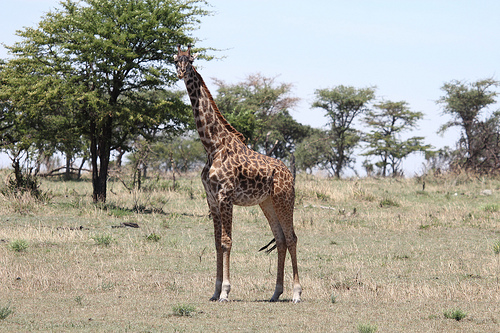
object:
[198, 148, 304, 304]
body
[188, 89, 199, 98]
spot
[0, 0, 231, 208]
trees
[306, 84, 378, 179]
trees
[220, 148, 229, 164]
spot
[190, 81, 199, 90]
spot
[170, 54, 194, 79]
face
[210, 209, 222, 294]
legs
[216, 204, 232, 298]
legs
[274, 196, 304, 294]
back legs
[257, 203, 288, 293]
back legs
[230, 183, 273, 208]
belly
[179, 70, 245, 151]
long neck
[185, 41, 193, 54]
horn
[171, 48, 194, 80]
head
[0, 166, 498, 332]
field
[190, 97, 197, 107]
spot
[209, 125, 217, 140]
spot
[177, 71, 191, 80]
mouth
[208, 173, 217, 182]
spot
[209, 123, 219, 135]
spot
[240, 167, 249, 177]
spot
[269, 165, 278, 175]
spot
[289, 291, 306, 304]
hooves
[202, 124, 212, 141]
spot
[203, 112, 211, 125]
spot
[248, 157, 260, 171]
spot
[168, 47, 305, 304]
giraffe